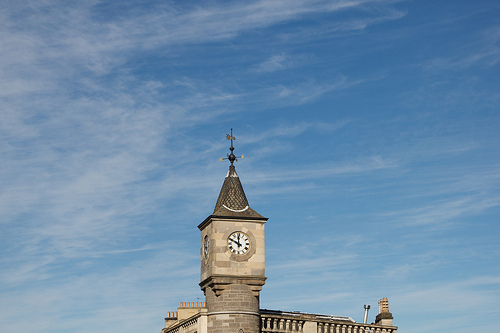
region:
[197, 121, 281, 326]
stone tower with white clock face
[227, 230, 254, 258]
round white clock face in stone tower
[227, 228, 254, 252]
black Roman numerals inside clock face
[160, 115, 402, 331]
top of chitch building with cross on top of tower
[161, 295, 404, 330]
top balcony of old chutch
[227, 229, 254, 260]
time reads11:50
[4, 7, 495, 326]
bright blue sunny almost cloudless sky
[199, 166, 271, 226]
brown pointed roof of clock tower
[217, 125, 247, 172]
weathrvane topped with cross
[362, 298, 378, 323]
modern silver object protruding from church roof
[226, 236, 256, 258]
white clock on tower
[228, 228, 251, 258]
roman numerals on clock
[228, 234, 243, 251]
black arms on clock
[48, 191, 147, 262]
whtie clouds in sky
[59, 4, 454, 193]
blue sky above tower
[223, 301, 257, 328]
stone bricks in tower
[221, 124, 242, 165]
weather vain on top of tower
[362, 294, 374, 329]
small rod sticking up from building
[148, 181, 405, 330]
top of castle like structure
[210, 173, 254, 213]
steeple on top of castle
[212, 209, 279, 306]
white clock on tower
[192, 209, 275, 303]
tower is grey brick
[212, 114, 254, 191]
weather vane on tower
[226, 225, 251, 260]
clock has roman numerals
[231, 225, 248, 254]
roman numerals are black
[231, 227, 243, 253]
clock has white face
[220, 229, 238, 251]
clock has black hands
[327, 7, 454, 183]
blue and white sky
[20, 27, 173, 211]
thin clouds in sky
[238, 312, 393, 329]
brown rail atop building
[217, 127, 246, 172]
black metal weather vane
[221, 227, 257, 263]
white clcok on a tower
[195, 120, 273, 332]
stone tower with weather vane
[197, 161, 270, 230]
roof of a stone tower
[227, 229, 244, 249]
black hands of a clock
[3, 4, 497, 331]
blue sky with wispy clouds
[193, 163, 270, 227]
black peaked roof on tower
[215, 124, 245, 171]
weather vane made of metal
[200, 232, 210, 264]
clock on a stone tower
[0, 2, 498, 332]
blue sky behind the tower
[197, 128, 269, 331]
steeple with a black roof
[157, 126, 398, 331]
steeple on top of a building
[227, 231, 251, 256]
steeple has a clock on it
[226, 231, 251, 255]
clock is round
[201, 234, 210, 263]
clock is round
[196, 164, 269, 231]
roof is black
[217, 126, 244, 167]
weather vane on the roof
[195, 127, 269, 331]
steeple is made of brick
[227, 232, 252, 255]
two clocks are on the steeple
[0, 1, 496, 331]
the sky is blue and clear